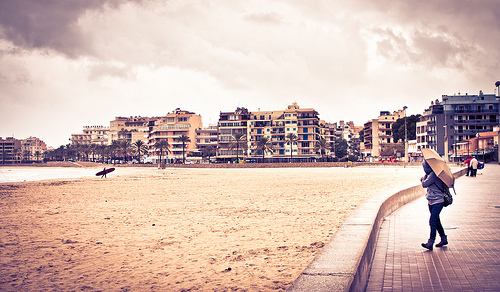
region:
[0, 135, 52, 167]
building is in background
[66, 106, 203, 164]
building is in background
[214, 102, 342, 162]
building is in background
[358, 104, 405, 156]
building is in background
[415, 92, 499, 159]
building is in background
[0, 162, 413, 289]
sand covers the ground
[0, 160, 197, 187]
water is next to the sand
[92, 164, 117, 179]
human holds surfboard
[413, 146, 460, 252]
human holds umbrella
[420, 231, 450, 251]
shoes are worn by human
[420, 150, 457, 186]
brown umbrella opened up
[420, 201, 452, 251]
blue jeans on woman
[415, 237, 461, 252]
black shoes on feet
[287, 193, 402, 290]
concrete wall by side walk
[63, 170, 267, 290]
sand on the beach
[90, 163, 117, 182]
person carrying surf board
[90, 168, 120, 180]
long board being carried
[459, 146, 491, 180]
couple walking on the beach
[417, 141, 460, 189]
Brown umbrella person is holding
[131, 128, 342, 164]
Palm trees in distance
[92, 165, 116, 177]
Surfboard person is carrying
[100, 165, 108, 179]
Person holding a surfboard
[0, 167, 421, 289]
Brown sand on beach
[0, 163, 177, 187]
Body of water next to beach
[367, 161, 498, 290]
Stone path next to beach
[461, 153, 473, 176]
Person in red shirt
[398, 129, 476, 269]
man is covered with an umbrella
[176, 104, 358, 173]
bulidings far away from the scene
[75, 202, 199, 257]
floor is brown in color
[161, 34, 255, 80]
sky covered with clouds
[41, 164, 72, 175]
water is colorles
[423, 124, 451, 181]
umbrlla is grey in color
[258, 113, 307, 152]
building window are blue in color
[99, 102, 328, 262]
background color is tarn yellow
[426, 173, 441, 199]
sweater is blue in color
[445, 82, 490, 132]
building is blue in color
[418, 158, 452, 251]
Person holding an umbrella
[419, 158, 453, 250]
Woman wearing a purple sweater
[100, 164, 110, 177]
Person carrying a surfboard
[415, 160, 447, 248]
Person carrying a backpack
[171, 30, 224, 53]
the sky is cloudy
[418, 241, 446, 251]
shoes on the feet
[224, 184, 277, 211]
sand on the beach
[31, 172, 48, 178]
water on the beach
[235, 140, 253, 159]
windows on the building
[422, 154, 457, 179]
the umbrella is held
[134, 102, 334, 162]
hotels near the beach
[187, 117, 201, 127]
the building is tan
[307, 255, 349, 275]
the curb is gray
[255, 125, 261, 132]
glass window on the building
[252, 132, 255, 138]
glass window on the building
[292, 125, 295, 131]
glass window on the building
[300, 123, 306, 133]
glass window on the building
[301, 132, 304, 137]
glass window on the building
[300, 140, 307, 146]
glass window on the building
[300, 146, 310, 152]
glass window on the building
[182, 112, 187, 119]
glass window on the building